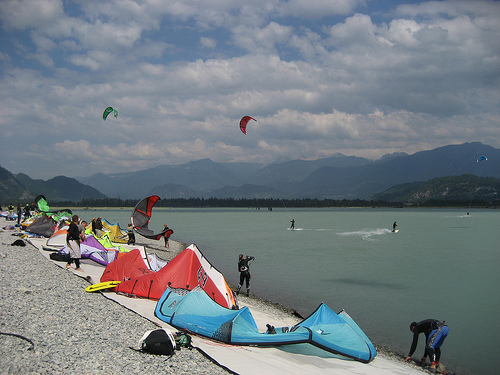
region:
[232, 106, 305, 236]
person kite surfing on the water.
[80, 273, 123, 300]
Yellow surfboard on the ground.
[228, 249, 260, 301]
person wearing a wetsuit.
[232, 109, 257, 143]
Red kite in the sky.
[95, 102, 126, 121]
Green kite in the sky.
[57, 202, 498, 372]
Water covering the surface.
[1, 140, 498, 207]
Mountains in the background.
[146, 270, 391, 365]
Blue kite on the ground.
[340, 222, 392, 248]
white splashes of water.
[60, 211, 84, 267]
Person in a black shirt.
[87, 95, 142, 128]
THE KITE IS GREEN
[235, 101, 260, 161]
THE KITE IS RED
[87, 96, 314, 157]
THE KITES ARE IN THE SKY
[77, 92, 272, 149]
THE KITES ARE FLYING HIGH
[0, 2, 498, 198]
THE SKY IS BLUE WITH MANY FLUFFY WHITE CLOUDS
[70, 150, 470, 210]
THE MOUNTAINS IN THE DISTANCE ARE MISTY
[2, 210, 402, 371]
THIS IS A BEACH WITH MANY KITES ON IT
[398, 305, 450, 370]
THIS GUY IS STANDING IN THE EDGE OF THE WATER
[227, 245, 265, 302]
THIS GIRL IS WEARING A WET SUIT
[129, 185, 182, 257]
THIS KITE IS READY TO BE FLOWN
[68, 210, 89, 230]
head of a person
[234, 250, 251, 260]
head of a person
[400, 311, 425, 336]
head of a person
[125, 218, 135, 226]
head of a person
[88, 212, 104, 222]
head of a person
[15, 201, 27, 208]
head of a person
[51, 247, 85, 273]
leg of a person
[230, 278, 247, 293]
leg of a person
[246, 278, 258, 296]
leg of a person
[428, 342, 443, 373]
leg of a person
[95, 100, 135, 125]
a blue kite in the sky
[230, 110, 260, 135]
a red kite in the sky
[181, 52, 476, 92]
the clouds in the sky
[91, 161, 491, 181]
mountains behind the water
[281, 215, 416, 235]
people wind surfing in the water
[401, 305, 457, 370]
a person bent down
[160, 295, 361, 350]
a blue kite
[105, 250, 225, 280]
a red kite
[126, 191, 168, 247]
a red and black kite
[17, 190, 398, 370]
kites on the ground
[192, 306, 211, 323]
the kite is blue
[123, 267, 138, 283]
the kite is red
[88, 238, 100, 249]
the kite is purple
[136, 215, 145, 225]
the kite is gray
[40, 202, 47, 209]
the kite is bright green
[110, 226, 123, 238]
the kite is orange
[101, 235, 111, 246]
the kite is yellow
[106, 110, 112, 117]
the kite is dark green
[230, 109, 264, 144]
the kite is inn the air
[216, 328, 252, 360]
the kite is on the tarp